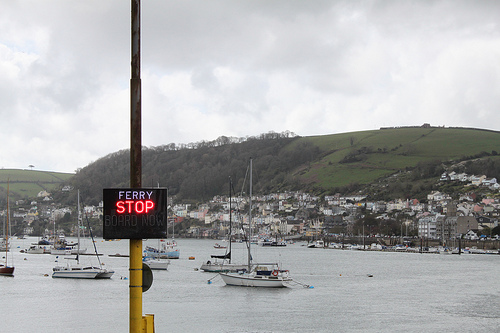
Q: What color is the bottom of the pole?
A: Yellow.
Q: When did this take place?
A: Daytime.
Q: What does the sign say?
A: Stop.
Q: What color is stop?
A: Red.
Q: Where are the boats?
A: In the water.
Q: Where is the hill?
A: Behind the water.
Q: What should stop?
A: Ferry.